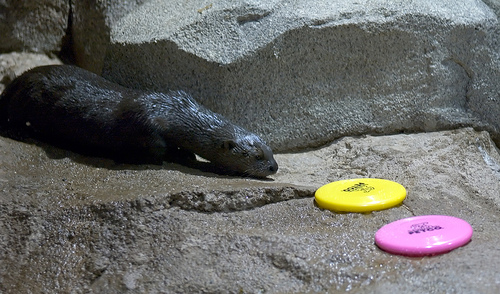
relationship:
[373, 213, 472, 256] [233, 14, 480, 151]
frisbee on boulder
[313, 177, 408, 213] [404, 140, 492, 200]
frisbee on boulder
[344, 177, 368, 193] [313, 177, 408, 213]
branding on frisbee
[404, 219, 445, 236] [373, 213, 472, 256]
branding on frisbee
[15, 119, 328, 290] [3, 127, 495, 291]
water on boulder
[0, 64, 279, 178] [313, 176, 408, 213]
animal examining frisbee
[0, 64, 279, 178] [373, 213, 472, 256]
animal examining frisbee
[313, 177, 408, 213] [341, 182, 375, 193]
frisbee with branding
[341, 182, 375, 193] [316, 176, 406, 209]
branding om top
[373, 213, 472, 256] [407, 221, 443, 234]
frisbee with branding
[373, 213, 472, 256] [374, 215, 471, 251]
frisbee on top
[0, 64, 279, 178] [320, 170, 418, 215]
animal near frisbee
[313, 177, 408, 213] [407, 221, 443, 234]
frisbee with branding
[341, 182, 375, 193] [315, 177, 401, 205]
branding on top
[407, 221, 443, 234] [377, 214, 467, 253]
branding on top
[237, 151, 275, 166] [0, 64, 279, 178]
eye of an animal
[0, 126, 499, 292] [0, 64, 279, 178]
boulder under an animal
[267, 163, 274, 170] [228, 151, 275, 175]
nostril on side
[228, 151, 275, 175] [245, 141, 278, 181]
side of an face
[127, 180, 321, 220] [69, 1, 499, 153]
crack in boulder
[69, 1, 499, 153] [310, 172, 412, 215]
boulder left of frisbee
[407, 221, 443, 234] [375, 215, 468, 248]
branding on top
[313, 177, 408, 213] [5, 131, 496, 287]
frisbee on ground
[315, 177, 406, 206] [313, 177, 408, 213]
top of frisbee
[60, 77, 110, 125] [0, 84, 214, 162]
fur on side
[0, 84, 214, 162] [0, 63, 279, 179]
side of animal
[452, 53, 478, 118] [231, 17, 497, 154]
crack in side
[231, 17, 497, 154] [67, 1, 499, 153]
side of boulder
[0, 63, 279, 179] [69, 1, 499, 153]
animal walking on boulder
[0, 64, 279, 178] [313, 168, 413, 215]
animal looking at frisbee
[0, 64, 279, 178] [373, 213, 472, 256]
animal looking at frisbee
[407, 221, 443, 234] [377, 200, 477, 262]
branding on frisbee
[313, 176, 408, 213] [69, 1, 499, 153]
frisbee on boulder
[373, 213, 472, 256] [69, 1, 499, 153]
frisbee on boulder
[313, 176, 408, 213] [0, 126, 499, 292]
frisbee on boulder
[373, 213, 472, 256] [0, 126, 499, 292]
frisbee on boulder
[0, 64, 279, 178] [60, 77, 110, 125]
animal has fur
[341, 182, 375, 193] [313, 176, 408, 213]
branding on frisbee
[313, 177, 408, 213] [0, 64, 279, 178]
frisbee for animal